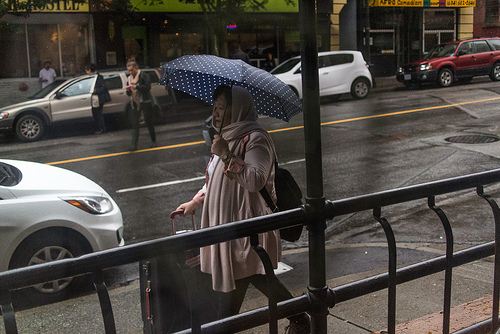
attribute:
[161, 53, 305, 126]
umbrella — blue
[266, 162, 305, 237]
bag — black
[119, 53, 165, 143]
girl — walking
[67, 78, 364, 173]
street — wet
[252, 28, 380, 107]
car — white, parked